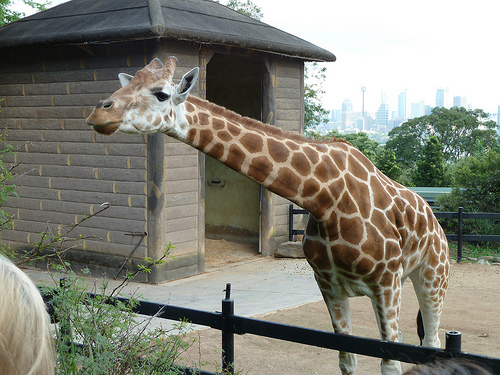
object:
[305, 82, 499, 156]
city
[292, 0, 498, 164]
background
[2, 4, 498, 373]
zoo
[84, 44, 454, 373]
giraffe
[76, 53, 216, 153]
ooking curious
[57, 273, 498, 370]
metal fence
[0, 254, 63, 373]
blonde hair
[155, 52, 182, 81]
horns on the giraffe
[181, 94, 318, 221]
he long neck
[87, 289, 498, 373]
fence is painted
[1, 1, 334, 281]
building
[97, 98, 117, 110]
lips and nostrils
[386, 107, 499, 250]
trees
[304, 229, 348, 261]
part of a chest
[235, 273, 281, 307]
part of a floor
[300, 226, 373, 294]
chest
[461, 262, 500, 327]
part of a groumd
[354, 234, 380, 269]
part of a chest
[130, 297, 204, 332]
part of a board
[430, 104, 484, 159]
part of a plant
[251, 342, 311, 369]
part of a ground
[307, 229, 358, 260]
part of a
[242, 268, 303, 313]
part of a grounmd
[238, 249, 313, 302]
part of a ground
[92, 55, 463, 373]
spotted giraffe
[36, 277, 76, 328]
hidden animal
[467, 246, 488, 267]
small stone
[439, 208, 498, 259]
low fenced area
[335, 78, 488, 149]
faint skycrappers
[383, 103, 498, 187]
green bushes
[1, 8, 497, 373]
an open space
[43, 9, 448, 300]
bright day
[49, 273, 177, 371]
green vegetation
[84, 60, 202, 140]
head of a giraffe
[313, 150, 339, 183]
brown spots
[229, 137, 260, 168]
white lines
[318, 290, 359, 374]
legs of the giraffe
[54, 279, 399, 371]
fence in front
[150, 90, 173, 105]
eye of the giraffe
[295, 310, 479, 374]
dirt under giraffe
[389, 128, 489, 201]
trees in the distanc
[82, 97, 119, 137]
nose and mouth